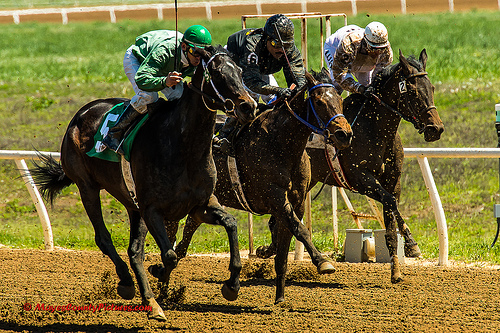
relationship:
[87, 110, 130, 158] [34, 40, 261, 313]
number on horse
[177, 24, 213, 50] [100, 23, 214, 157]
helmet on jockey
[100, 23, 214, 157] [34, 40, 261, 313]
jockey on horse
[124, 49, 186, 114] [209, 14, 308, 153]
pants on jockey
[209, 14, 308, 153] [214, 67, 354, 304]
jockey on horse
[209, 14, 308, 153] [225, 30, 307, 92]
jockey wearing jacket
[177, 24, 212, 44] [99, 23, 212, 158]
helmet on jockey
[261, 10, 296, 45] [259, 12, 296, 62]
helmet on head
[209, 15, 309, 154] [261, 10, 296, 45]
jockey wearing helmet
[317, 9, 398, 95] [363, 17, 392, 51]
jockey wearing helmet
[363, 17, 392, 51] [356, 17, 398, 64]
helmet on head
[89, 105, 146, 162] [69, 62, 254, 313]
saddle on horse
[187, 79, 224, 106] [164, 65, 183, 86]
reins are in hands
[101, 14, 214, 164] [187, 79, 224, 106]
jockey holding reins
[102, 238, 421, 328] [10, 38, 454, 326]
hooves are on horses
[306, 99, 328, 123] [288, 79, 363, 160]
horse bridle on horse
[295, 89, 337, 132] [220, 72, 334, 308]
horse bridle on horse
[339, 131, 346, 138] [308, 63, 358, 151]
nostril on horse's face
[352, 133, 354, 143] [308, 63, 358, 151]
nostril on horse's face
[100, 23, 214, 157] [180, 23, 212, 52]
jockey wearing helmet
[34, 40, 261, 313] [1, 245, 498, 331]
horse racing on track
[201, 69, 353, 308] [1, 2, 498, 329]
horse racing on track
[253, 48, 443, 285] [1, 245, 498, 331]
horse racing on track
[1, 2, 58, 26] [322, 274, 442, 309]
post in ground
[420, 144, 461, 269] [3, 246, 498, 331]
post in ground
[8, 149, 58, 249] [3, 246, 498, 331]
post in ground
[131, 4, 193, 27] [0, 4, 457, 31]
post in ground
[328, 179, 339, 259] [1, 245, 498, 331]
metal post in dirt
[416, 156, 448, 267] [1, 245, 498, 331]
post in dirt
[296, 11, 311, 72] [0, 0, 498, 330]
post in dirt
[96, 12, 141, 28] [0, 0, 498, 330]
post in dirt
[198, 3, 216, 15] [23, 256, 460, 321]
post in dirt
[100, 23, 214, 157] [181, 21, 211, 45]
jockey wearing helmet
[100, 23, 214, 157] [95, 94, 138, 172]
jockey wearing boots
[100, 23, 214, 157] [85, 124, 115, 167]
jockey wearing boots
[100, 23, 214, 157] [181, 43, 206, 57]
jockey wearing glasses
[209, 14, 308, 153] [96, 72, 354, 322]
jockey riding horse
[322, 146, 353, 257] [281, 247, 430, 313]
post in dirt